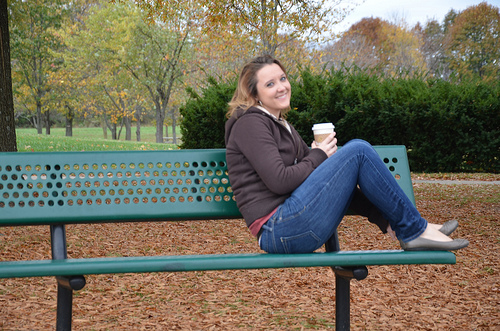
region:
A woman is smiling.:
[233, 59, 308, 122]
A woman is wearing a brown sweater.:
[225, 118, 315, 202]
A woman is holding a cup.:
[297, 108, 353, 153]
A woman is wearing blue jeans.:
[289, 143, 400, 244]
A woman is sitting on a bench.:
[216, 58, 363, 282]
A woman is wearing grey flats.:
[401, 211, 470, 252]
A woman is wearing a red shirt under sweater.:
[237, 193, 284, 243]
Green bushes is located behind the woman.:
[336, 74, 499, 159]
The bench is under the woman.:
[33, 135, 237, 279]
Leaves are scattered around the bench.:
[16, 235, 496, 312]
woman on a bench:
[213, 46, 465, 262]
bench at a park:
[5, 119, 471, 329]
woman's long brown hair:
[221, 50, 285, 125]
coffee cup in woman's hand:
[309, 110, 342, 161]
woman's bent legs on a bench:
[256, 134, 471, 266]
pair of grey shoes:
[405, 209, 469, 254]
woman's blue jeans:
[250, 133, 433, 254]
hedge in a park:
[167, 49, 498, 181]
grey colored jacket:
[221, 97, 331, 229]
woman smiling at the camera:
[209, 45, 475, 257]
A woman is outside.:
[0, 2, 496, 327]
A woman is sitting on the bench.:
[210, 45, 470, 258]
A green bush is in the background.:
[180, 56, 497, 166]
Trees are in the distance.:
[15, 0, 185, 143]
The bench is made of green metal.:
[1, 140, 456, 327]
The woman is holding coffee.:
[310, 117, 340, 154]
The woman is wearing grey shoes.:
[397, 210, 468, 251]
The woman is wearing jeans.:
[231, 136, 426, 251]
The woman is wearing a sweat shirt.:
[221, 101, 326, 224]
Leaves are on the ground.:
[110, 277, 307, 325]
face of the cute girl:
[232, 45, 326, 135]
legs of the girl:
[384, 220, 469, 250]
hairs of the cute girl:
[218, 63, 258, 121]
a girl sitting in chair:
[181, 36, 467, 284]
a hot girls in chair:
[185, 13, 495, 321]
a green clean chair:
[20, 138, 403, 283]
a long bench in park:
[16, 136, 497, 307]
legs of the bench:
[319, 268, 375, 329]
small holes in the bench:
[77, 160, 108, 171]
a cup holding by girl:
[314, 110, 359, 178]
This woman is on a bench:
[176, 29, 458, 264]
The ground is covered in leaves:
[102, 277, 332, 329]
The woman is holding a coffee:
[308, 117, 346, 158]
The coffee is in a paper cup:
[309, 117, 338, 154]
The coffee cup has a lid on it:
[305, 116, 339, 133]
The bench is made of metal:
[8, 145, 240, 277]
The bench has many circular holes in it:
[11, 156, 218, 203]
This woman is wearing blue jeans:
[262, 139, 442, 241]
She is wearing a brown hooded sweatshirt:
[220, 95, 315, 213]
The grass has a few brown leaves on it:
[20, 133, 167, 152]